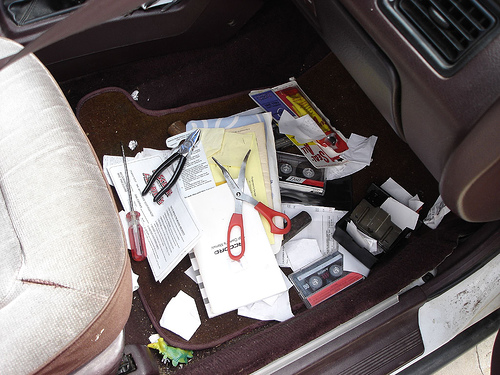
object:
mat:
[80, 76, 367, 350]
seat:
[0, 35, 132, 373]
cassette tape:
[277, 151, 327, 198]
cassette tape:
[288, 247, 363, 310]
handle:
[256, 202, 288, 233]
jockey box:
[310, 0, 405, 143]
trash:
[126, 88, 141, 100]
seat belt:
[0, 0, 156, 71]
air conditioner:
[376, 0, 500, 79]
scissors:
[210, 148, 290, 260]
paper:
[340, 131, 378, 166]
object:
[142, 333, 193, 367]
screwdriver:
[120, 143, 147, 261]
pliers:
[141, 128, 201, 202]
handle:
[125, 208, 147, 260]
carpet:
[75, 79, 447, 352]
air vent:
[372, 0, 498, 78]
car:
[0, 0, 500, 374]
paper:
[160, 288, 203, 342]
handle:
[226, 211, 244, 262]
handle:
[140, 153, 176, 195]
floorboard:
[72, 39, 477, 353]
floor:
[54, 49, 477, 374]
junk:
[424, 196, 449, 232]